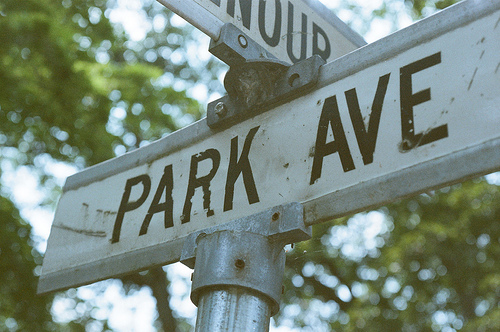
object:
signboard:
[35, 0, 499, 294]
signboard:
[158, 0, 363, 60]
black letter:
[110, 51, 448, 249]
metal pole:
[188, 283, 276, 331]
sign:
[153, 0, 345, 69]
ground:
[414, 172, 416, 190]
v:
[336, 69, 389, 166]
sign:
[26, 0, 500, 293]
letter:
[220, 119, 262, 213]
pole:
[190, 233, 288, 330]